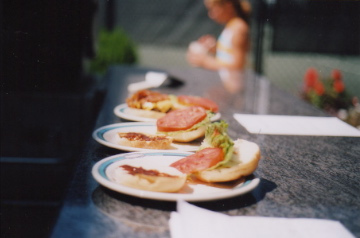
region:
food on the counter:
[90, 34, 258, 210]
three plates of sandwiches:
[95, 71, 250, 226]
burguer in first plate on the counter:
[119, 134, 258, 190]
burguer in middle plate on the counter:
[118, 108, 211, 145]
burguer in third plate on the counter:
[128, 88, 216, 111]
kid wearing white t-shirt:
[191, 0, 251, 70]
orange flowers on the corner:
[301, 68, 346, 99]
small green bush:
[87, 25, 134, 85]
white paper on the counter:
[230, 105, 358, 133]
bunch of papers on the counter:
[163, 205, 356, 236]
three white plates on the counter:
[84, 91, 259, 204]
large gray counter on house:
[45, 54, 359, 236]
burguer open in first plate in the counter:
[106, 128, 265, 188]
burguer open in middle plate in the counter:
[90, 115, 228, 150]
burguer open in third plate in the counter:
[129, 87, 209, 112]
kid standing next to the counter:
[196, 0, 249, 74]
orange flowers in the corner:
[305, 71, 347, 100]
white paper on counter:
[230, 108, 359, 139]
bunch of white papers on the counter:
[165, 198, 351, 231]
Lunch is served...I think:
[91, 87, 260, 201]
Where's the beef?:
[91, 84, 263, 202]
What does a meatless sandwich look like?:
[93, 84, 267, 201]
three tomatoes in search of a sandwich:
[92, 88, 264, 202]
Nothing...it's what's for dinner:
[91, 87, 264, 201]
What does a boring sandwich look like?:
[91, 88, 263, 200]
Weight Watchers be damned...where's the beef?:
[93, 88, 263, 200]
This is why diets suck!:
[91, 87, 262, 206]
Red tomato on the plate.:
[179, 137, 220, 179]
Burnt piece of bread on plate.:
[124, 160, 180, 191]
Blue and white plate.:
[85, 140, 289, 203]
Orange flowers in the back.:
[300, 64, 349, 100]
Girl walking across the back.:
[184, 10, 265, 74]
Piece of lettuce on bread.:
[209, 113, 246, 169]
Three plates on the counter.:
[121, 77, 261, 210]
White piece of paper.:
[236, 95, 349, 156]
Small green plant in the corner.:
[73, 17, 142, 62]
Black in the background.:
[16, 119, 60, 197]